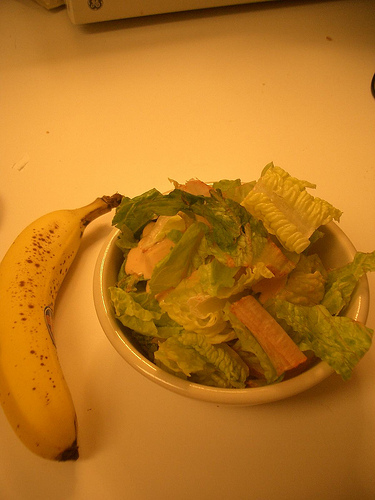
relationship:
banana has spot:
[1, 193, 122, 463] [30, 350, 38, 356]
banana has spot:
[1, 193, 122, 463] [46, 228, 54, 235]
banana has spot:
[1, 193, 122, 463] [27, 303, 35, 309]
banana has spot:
[1, 193, 122, 463] [31, 385, 38, 393]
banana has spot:
[1, 193, 122, 463] [35, 262, 41, 268]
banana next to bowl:
[1, 193, 122, 463] [94, 182, 370, 408]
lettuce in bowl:
[240, 166, 343, 254] [94, 182, 370, 408]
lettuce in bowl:
[275, 300, 374, 383] [94, 182, 370, 408]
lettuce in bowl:
[150, 223, 206, 298] [94, 182, 370, 408]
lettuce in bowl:
[111, 188, 211, 236] [94, 182, 370, 408]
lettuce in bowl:
[153, 337, 207, 377] [94, 182, 370, 408]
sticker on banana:
[42, 307, 56, 350] [1, 193, 122, 463]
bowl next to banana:
[94, 182, 370, 408] [1, 193, 122, 463]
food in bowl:
[108, 163, 373, 387] [94, 182, 370, 408]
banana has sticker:
[1, 193, 122, 463] [42, 307, 56, 350]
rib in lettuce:
[255, 181, 313, 238] [240, 166, 343, 254]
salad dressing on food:
[125, 221, 178, 281] [108, 163, 373, 387]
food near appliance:
[108, 163, 373, 387] [39, 0, 269, 27]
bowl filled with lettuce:
[94, 182, 370, 408] [240, 166, 343, 254]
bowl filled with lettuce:
[94, 182, 370, 408] [275, 300, 374, 383]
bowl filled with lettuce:
[94, 182, 370, 408] [153, 337, 207, 377]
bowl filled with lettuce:
[94, 182, 370, 408] [150, 223, 206, 298]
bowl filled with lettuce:
[94, 182, 370, 408] [111, 188, 211, 236]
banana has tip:
[1, 193, 122, 463] [100, 192, 127, 208]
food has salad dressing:
[108, 163, 373, 387] [125, 221, 178, 281]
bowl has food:
[94, 182, 370, 408] [108, 163, 373, 387]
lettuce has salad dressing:
[150, 223, 206, 298] [125, 221, 178, 281]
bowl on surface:
[94, 182, 370, 408] [1, 27, 374, 163]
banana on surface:
[1, 193, 122, 463] [0, 0, 374, 499]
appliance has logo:
[39, 0, 269, 27] [88, 1, 104, 11]